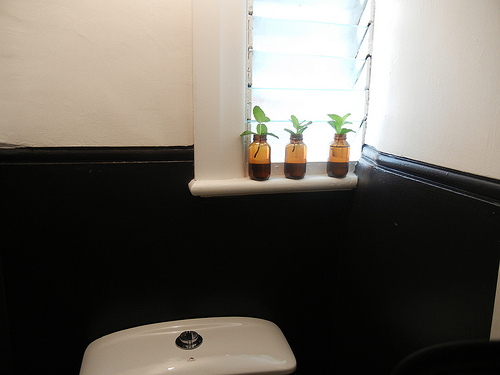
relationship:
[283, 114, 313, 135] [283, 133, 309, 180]
middle plant in a jar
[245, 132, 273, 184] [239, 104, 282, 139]
jar for plant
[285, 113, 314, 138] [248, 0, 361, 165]
middle plant in window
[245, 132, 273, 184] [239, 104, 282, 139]
jar with plant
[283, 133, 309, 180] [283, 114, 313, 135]
jar with middle plant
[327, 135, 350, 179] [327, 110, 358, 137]
jar with plant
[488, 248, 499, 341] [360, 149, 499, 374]
object against right wall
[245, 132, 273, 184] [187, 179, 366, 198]
jar on window sill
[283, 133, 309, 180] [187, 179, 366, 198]
jar on window sill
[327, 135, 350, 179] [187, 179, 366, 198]
jar on window sill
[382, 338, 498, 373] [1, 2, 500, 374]
object in bathroom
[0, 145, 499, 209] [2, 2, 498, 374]
moulding around walls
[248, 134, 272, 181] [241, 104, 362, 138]
jar with plants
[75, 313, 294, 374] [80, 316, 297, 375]
top of toilet tank lit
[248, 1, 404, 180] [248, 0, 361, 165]
sunlight shining in window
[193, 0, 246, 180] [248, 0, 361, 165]
moulding by window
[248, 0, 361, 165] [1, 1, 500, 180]
window in wall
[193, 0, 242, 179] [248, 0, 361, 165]
frame on window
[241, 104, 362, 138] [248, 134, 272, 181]
plants in jar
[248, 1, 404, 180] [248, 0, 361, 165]
sunlight shining through window